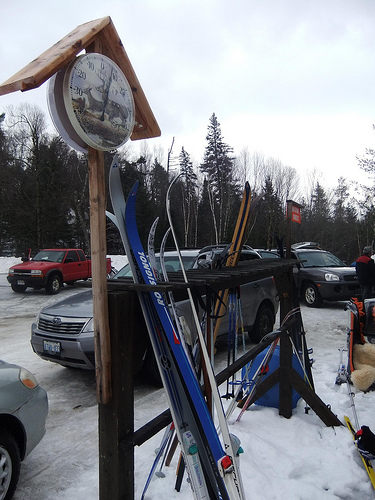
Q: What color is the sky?
A: Blue.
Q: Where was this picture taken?
A: A ski shop.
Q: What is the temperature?
A: 8 degrees.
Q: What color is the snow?
A: White.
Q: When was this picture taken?
A: Daytime.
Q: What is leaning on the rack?
A: Skis.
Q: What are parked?
A: Cars.